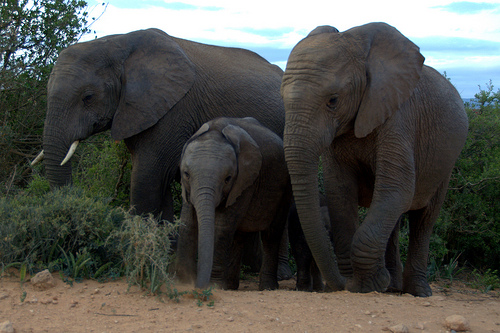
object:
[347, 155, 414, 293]
leg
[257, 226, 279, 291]
leg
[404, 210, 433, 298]
leg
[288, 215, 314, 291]
leg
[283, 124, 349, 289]
trunks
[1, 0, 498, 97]
sky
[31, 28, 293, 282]
elephants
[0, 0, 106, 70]
trees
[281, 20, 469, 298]
elephant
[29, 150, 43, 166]
tusk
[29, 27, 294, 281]
poppa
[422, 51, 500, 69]
clouds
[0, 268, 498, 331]
brown dirt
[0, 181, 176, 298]
exotic weed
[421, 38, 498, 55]
patches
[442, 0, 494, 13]
patches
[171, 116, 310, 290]
baby elephant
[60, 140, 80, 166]
tusks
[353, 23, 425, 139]
ear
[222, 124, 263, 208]
ear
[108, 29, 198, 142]
ear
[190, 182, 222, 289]
trunk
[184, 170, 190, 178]
eye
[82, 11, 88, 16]
leaf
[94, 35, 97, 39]
leaf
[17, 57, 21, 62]
leaf